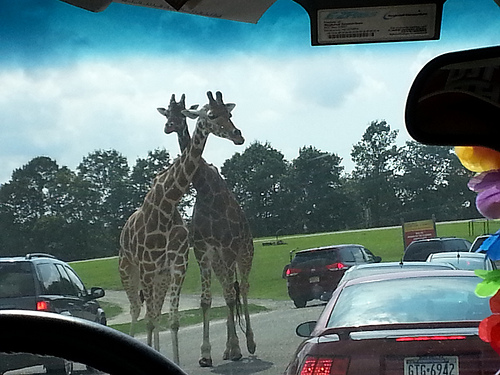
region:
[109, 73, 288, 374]
two giraffes walking on street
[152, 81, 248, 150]
two large heads of giraffes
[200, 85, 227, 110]
brown horns on giraffe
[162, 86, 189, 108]
brown horns on giraffe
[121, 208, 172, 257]
brown spots on giraffe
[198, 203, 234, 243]
brown spots on girafe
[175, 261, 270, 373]
log legs of giraffe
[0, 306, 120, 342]
black steering wheel of car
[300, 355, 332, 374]
red light on car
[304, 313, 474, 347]
spoiler on back of car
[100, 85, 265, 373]
Two giraffes on a busy road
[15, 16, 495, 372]
The giraffes are walking around the cars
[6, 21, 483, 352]
The giraffes are in a game reserve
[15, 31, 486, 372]
The giraffes are on display for visitors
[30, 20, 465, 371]
The giraffes are male and female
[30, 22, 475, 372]
The giraffes are looking for food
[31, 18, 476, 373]
The giraffes are out in the daytime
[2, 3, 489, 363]
The people are enjoying the giraffes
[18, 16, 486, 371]
The cars are moving very slowly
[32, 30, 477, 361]
The cars are careful not to hit anything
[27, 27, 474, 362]
The people are enjoying their day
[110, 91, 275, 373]
two giraffes in the road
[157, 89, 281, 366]
giraffe in the road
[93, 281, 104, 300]
side view mirror on the car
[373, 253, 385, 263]
side view mirror on the car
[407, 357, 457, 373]
license plate on the car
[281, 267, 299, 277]
brake light on the car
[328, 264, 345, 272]
brake light on the car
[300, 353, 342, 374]
brake light on the car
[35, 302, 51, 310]
brake light on the car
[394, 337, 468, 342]
brake light on car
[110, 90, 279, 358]
Two giraffes in middle of road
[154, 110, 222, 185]
Giraffes' necks are crossed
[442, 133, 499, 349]
Lei hanging from rear view window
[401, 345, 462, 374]
License plate of car in front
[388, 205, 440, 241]
Sign for park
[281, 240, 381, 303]
Black car parked by side of road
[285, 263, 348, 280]
Parking lights lit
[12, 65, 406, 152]
Partly cloudy weather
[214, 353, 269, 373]
Shadow on ground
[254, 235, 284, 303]
Green grass in nearby field